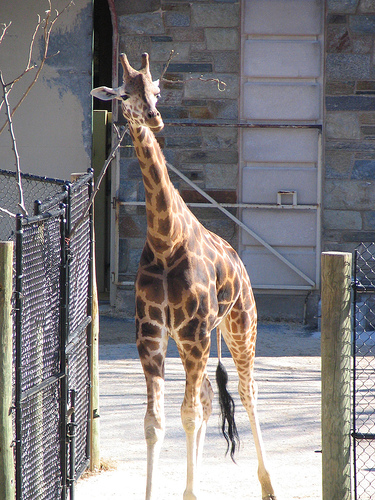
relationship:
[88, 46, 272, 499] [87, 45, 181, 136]
giraffe has head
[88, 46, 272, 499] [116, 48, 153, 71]
giraffe has horns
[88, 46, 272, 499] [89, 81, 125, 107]
giraffe has ear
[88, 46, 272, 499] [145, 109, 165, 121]
giraffe has nose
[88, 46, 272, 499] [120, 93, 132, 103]
giraffe has right eye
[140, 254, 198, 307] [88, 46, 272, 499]
pattern on giraffe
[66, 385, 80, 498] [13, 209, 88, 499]
bar on top of door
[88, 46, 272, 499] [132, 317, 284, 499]
giraffe has four legs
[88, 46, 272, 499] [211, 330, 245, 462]
giraffe has tail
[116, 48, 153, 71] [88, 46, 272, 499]
horns on top of giraffe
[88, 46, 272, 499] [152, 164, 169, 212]
giraffe has spots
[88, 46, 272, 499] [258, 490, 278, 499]
giraffe has hoof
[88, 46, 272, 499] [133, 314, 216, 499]
giraffe has front legs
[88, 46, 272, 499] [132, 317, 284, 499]
giraffe has legs